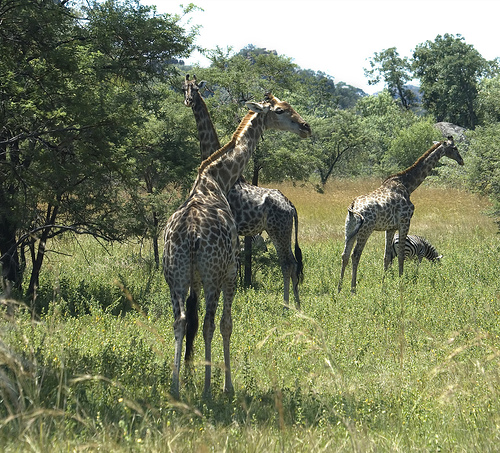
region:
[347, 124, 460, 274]
tan and brown spotted giraffe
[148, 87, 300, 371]
tan and brown spotted giraffe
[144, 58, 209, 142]
tan and brown spotted giraffe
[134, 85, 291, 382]
tan and brown giraffe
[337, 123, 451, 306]
tan and brown giraffe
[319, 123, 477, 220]
tan and brown giraffe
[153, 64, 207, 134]
tan and brown giraffe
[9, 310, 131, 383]
long brown and green grass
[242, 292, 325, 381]
long brown and green grass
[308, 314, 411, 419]
long brown and green grass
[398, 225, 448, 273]
The zebra on the right.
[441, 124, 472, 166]
The head of the giraffe next to the zebra.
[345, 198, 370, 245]
The tail of the giraffe next to the zebra.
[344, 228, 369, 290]
The back legs of the giraffe next to the zebra.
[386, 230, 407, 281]
The front legs of the giraffe next to the zebra.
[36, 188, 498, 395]
The grass area where the giraffes and zebra are standing.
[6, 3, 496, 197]
The trees in the distance.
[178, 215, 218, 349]
The tail of the giraffe facing right.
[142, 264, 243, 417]
The legs of the giraffe facing right.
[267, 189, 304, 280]
The tail of the giraffe facing towards the camera.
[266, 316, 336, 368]
short green yellow and brown grass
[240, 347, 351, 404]
short green yellow and brown grass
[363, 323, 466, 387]
short green yellow and brown grass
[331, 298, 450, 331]
short green yellow and brown grass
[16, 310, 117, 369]
short green yellow and brown grass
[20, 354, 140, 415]
short green yellow and brown grass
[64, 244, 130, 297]
short green yellow and brown grass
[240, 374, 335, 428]
short green yellow and brown grass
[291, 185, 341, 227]
short green yellow and brown grass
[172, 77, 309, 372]
Giraffes standing in the open field.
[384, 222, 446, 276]
A zebra eating grass.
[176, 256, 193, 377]
The giraffe has a long black tail.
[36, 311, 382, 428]
The grass is tall and green.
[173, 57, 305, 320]
The giraffe is brown and white.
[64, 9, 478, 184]
Trees in the background.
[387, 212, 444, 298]
The zebra is black and white.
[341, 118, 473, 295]
The zebra is standing next to the giraffe.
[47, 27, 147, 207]
Leaves on the trees.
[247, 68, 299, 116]
The giraffe has horns on top of head.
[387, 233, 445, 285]
A lone zebra eating grass.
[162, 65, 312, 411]
Two adult giraffes in the grass.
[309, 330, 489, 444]
Tall grass and tiny flowers.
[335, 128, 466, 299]
A zebra and a giraffe.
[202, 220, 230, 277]
Brown spots on a yellow hide.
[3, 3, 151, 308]
A tall scrubby tree next to the animals.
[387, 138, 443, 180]
A brown mane on a giraffe.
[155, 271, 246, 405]
Four giraffe legs.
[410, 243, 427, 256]
Black and white stripes.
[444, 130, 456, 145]
Dark horns on a giraffe.